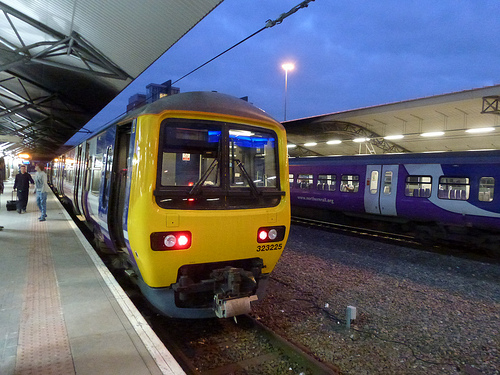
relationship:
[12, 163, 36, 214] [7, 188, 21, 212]
person pulling luggage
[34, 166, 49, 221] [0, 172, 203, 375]
person standing in platform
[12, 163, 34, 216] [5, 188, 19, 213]
person rolling luggage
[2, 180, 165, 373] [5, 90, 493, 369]
platform in train station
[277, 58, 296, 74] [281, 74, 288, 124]
light on pole